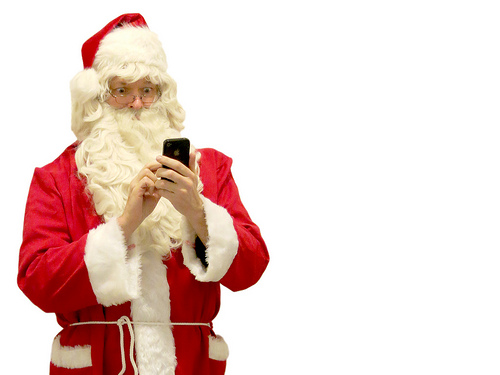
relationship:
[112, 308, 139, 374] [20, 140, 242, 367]
string around coat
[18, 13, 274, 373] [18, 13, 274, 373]
man dressed as man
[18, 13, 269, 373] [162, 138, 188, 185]
man holding cellphone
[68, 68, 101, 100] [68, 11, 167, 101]
ball on hat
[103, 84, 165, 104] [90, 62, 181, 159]
eyeglasses on face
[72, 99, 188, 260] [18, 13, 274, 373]
beard on man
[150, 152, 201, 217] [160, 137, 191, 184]
hand holding cell phone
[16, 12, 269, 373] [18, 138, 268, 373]
costume on coat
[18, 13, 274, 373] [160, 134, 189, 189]
man holds a cellphone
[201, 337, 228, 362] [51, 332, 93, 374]
trim on pocket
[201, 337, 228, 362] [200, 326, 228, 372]
trim on pocket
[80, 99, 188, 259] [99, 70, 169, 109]
beard on face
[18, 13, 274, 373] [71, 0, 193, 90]
man has cap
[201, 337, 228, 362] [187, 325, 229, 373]
trim on pocket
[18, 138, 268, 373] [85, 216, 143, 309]
coat has cuff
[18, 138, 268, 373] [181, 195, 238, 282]
coat has cuff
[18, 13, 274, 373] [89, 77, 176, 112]
man wearing eyeglasses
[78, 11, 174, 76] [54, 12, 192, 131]
cap on head